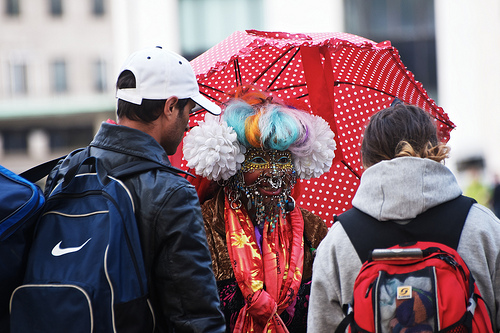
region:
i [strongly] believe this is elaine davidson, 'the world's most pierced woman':
[170, 87, 339, 332]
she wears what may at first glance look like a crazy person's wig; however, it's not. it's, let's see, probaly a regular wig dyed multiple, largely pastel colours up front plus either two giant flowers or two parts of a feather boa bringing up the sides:
[172, 86, 338, 194]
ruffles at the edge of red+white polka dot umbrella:
[156, 19, 465, 249]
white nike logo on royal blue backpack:
[42, 228, 100, 264]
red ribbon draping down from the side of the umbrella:
[296, 41, 349, 178]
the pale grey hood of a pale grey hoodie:
[345, 154, 467, 226]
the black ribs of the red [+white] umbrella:
[185, 32, 440, 210]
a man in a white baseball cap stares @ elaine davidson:
[103, 34, 227, 131]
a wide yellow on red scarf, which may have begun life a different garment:
[223, 191, 307, 332]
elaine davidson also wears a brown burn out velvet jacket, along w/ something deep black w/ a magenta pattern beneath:
[193, 196, 345, 331]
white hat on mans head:
[135, 52, 187, 97]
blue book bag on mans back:
[75, 197, 116, 236]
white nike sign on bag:
[45, 236, 98, 261]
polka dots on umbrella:
[223, 38, 238, 51]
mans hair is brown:
[377, 114, 412, 136]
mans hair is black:
[134, 105, 159, 119]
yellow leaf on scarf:
[233, 231, 253, 253]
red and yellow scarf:
[273, 235, 288, 285]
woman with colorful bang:
[231, 106, 302, 150]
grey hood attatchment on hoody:
[371, 166, 443, 201]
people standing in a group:
[23, 66, 430, 308]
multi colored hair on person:
[207, 66, 351, 156]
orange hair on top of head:
[194, 88, 291, 150]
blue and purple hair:
[247, 107, 301, 147]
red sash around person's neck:
[234, 211, 316, 308]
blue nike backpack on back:
[60, 161, 140, 321]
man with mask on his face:
[234, 145, 299, 213]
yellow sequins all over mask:
[243, 141, 287, 181]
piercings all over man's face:
[171, 186, 310, 236]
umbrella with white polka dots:
[236, 19, 353, 81]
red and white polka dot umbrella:
[179, 30, 454, 244]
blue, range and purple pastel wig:
[222, 101, 317, 151]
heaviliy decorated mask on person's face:
[232, 150, 296, 222]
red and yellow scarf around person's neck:
[222, 190, 307, 331]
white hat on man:
[107, 44, 222, 115]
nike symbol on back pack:
[47, 237, 97, 258]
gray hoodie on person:
[304, 158, 497, 330]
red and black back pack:
[327, 195, 494, 332]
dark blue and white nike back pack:
[1, 147, 160, 329]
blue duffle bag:
[1, 147, 79, 276]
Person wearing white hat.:
[138, 39, 193, 109]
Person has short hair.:
[132, 81, 174, 145]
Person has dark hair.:
[116, 62, 205, 137]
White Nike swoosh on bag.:
[44, 207, 119, 320]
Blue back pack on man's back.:
[15, 174, 155, 296]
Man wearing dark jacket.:
[168, 192, 198, 317]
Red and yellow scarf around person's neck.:
[226, 229, 291, 319]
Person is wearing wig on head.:
[218, 100, 365, 155]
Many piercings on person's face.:
[250, 164, 308, 224]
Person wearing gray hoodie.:
[376, 145, 425, 259]